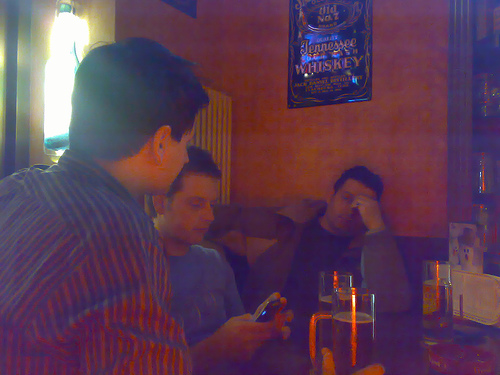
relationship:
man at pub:
[273, 160, 404, 330] [5, 11, 497, 346]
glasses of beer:
[313, 241, 431, 373] [303, 270, 456, 367]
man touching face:
[300, 160, 403, 308] [323, 180, 382, 229]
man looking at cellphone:
[159, 165, 288, 355] [256, 286, 278, 343]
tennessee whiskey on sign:
[300, 39, 369, 71] [287, 7, 379, 109]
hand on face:
[352, 187, 394, 239] [323, 180, 382, 229]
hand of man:
[352, 187, 394, 239] [300, 160, 403, 308]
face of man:
[323, 180, 382, 229] [300, 160, 403, 308]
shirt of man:
[17, 161, 177, 370] [11, 75, 221, 374]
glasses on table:
[313, 241, 431, 373] [267, 251, 496, 332]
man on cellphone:
[159, 165, 288, 355] [256, 286, 278, 343]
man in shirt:
[159, 165, 288, 355] [170, 239, 249, 342]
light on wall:
[55, 23, 88, 154] [25, 16, 474, 222]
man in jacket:
[300, 160, 403, 308] [345, 232, 411, 296]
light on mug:
[352, 297, 364, 354] [331, 286, 370, 364]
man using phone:
[159, 165, 288, 355] [251, 290, 292, 330]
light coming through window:
[55, 23, 88, 154] [21, 1, 99, 169]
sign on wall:
[287, 7, 379, 109] [25, 16, 474, 222]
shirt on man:
[17, 161, 177, 370] [300, 160, 403, 308]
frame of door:
[2, 7, 33, 168] [1, 13, 34, 165]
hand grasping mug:
[316, 345, 378, 374] [331, 286, 370, 364]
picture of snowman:
[436, 227, 486, 270] [458, 225, 476, 269]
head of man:
[323, 180, 382, 229] [300, 160, 403, 308]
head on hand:
[323, 166, 383, 230] [352, 187, 394, 239]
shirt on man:
[170, 239, 249, 342] [159, 165, 288, 355]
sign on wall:
[287, 0, 379, 109] [25, 16, 474, 222]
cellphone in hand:
[256, 286, 278, 343] [207, 306, 262, 357]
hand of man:
[207, 306, 262, 357] [159, 165, 288, 355]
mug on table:
[331, 286, 370, 364] [267, 251, 496, 332]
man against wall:
[300, 160, 403, 308] [25, 16, 474, 222]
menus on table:
[446, 266, 500, 311] [267, 251, 496, 332]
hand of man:
[316, 345, 378, 374] [11, 75, 221, 374]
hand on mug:
[316, 345, 378, 374] [331, 286, 370, 364]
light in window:
[55, 23, 88, 154] [21, 1, 99, 169]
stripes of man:
[17, 161, 177, 370] [11, 75, 221, 374]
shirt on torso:
[286, 226, 342, 283] [268, 225, 354, 327]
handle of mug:
[304, 313, 323, 373] [331, 286, 370, 364]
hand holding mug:
[316, 345, 378, 374] [331, 286, 370, 364]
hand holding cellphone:
[207, 306, 262, 357] [256, 286, 278, 343]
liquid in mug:
[325, 309, 382, 371] [311, 286, 370, 373]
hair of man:
[74, 56, 216, 158] [11, 75, 221, 374]